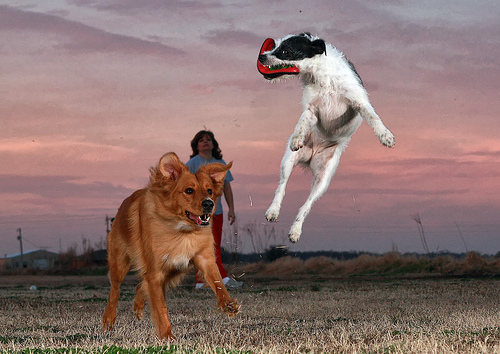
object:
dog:
[259, 30, 396, 242]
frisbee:
[256, 37, 300, 79]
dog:
[102, 153, 241, 337]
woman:
[185, 128, 244, 289]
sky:
[1, 4, 497, 259]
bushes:
[220, 243, 380, 260]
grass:
[1, 257, 497, 354]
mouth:
[263, 56, 299, 79]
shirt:
[187, 153, 234, 215]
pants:
[195, 211, 227, 282]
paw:
[290, 135, 304, 152]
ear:
[313, 37, 327, 57]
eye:
[282, 50, 290, 55]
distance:
[25, 233, 464, 283]